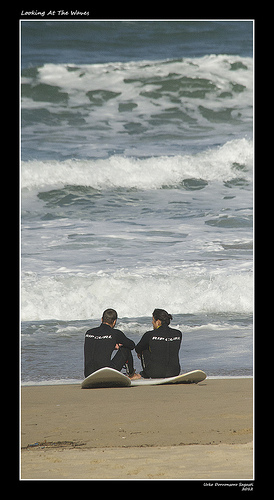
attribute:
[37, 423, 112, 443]
sand — smooth , tan 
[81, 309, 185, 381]
people — sitting, looking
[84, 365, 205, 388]
surfboards — white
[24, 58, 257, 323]
seafoam — white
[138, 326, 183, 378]
wetsuit — black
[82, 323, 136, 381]
wetsuit — black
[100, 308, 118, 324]
hair — short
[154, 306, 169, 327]
hair — short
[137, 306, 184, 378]
woman — sitting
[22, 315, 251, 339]
wave — small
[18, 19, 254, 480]
picture — sunny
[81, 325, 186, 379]
wetsuits — black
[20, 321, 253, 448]
sand — wet, brown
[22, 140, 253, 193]
wave — white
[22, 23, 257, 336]
water — blue, wavy, white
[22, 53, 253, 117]
wave — rolling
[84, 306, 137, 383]
person — sitting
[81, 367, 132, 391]
surfboard — white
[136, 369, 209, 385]
surfboard — white